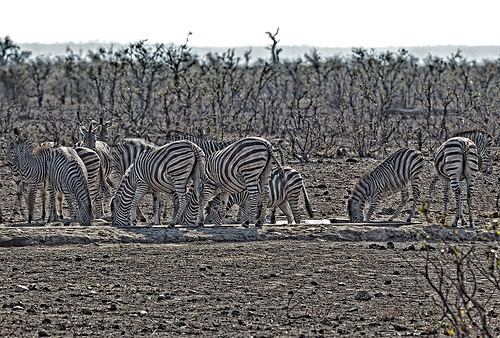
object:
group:
[4, 117, 499, 230]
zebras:
[108, 139, 207, 227]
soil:
[0, 241, 499, 336]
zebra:
[342, 147, 427, 224]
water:
[264, 216, 344, 225]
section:
[267, 60, 397, 130]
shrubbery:
[278, 113, 327, 163]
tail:
[416, 147, 430, 184]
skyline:
[0, 40, 500, 49]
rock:
[353, 288, 372, 303]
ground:
[0, 241, 499, 337]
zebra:
[432, 124, 485, 228]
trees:
[23, 53, 61, 108]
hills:
[195, 45, 270, 67]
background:
[0, 0, 480, 65]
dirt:
[0, 145, 499, 335]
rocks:
[2, 228, 35, 244]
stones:
[174, 227, 238, 243]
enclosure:
[0, 225, 499, 245]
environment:
[6, 36, 500, 333]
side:
[343, 147, 425, 222]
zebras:
[46, 146, 96, 226]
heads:
[76, 122, 103, 152]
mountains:
[0, 42, 495, 68]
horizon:
[0, 39, 500, 52]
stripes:
[238, 165, 265, 176]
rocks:
[285, 290, 299, 297]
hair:
[304, 198, 316, 218]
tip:
[304, 203, 318, 218]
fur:
[12, 128, 20, 137]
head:
[0, 127, 20, 175]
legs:
[128, 181, 150, 226]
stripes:
[170, 177, 189, 184]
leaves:
[238, 92, 245, 99]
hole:
[75, 209, 429, 225]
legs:
[239, 170, 262, 228]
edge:
[275, 217, 368, 225]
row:
[419, 44, 447, 63]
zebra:
[0, 137, 55, 226]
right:
[347, 70, 497, 240]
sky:
[0, 0, 500, 47]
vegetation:
[386, 198, 499, 337]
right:
[418, 45, 498, 325]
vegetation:
[0, 27, 499, 163]